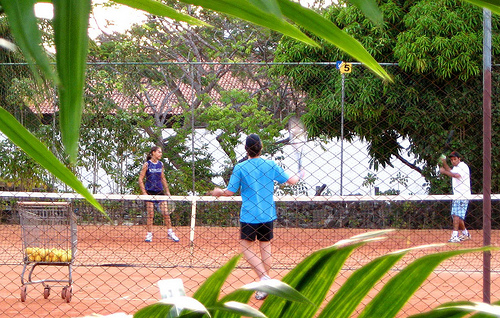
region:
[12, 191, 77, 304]
Shopping cart holding tennis balls.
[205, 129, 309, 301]
Person in blue shirt swinging a tennis racket.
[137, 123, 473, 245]
Two people on the same side of a tennis court.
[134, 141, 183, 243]
Girl in a purple shirt playing tennis.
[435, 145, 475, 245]
Man in shorts holding a tennis ball.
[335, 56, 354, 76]
Yellow sign with the number five on it.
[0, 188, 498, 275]
Tennis net dividing the court.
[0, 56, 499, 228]
Chain link fence.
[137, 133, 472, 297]
Three people involved in playing tennis.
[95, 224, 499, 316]
Long leaves of a plant.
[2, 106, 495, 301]
three people on a tennis court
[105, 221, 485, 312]
green plant in the foreground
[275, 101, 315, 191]
tennis racket in person's right hand appears to be in motion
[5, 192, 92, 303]
shopping cart with tennis balls inside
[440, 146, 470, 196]
man wearing white shirt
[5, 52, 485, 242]
chain-link fence behind players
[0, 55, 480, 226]
structure behind fence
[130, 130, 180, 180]
female looking to her left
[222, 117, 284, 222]
person wearing a blue shirt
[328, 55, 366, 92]
number affixed to top of fence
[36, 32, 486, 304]
Three people on tennis court.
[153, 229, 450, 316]
Green leaves in foreground.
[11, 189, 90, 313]
A grocery cart.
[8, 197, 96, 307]
Grocery cart with yellow tennis balls.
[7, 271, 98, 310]
Four wheels on cart.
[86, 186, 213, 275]
Dark tennis net with white top.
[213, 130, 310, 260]
Person in light blue shirt.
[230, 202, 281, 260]
A pair of black pants.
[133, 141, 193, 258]
A girl playing tennis.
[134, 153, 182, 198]
A tank top with white letters.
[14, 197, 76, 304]
a shopping cart full of tennis balls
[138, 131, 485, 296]
three people playing tennis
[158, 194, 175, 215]
a girl's tennis racket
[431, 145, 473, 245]
a man holding a tennis ball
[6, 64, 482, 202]
a metal fence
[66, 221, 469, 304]
a tennis court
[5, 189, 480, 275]
a net in a tennis court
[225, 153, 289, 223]
a man's t-shirt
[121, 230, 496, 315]
a leafy green plant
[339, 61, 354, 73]
a number 5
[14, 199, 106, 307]
Shopping cart with tennis balls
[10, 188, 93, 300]
Shopping cart full of green balls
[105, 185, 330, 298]
Next in a tennis court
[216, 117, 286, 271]
Man wearing a blue shirt and black shorts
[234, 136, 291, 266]
Man standing in a tennis court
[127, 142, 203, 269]
Woman with a dark blue shirt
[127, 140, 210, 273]
Woman holding a tennis racquet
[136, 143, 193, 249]
Woman standing on a tennis court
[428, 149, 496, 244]
Man with a white shirt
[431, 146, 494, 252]
Man serving a tennis ball